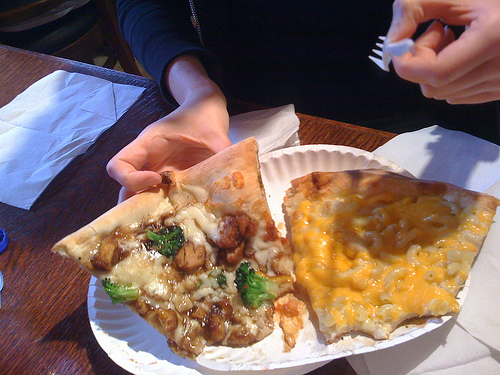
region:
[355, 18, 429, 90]
white plastic fork in hand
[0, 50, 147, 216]
white napkin on wooden table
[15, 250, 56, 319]
wooden surface of table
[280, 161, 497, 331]
macaroni and cheese pizza slive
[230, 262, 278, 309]
green broccoli on pizza slice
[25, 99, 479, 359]
pizza slices on white paper plate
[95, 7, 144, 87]
brown wooden chair leg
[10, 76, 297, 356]
pizza slice being held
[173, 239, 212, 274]
cooked brown mushroom on pizza slice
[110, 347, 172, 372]
food stain on white paper plate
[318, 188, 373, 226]
sauce on a pizza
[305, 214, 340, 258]
sauce on a pizza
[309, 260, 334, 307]
sauce on a pizza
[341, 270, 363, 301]
sauce on a pizza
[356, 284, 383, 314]
sauce on a pizza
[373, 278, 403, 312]
sauce on a pizza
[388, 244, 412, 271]
sauce on a pizza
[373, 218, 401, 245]
sauce on a pizza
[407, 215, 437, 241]
sauce on a pizza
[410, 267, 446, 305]
sauce on a pizza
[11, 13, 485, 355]
Two slices of pizza.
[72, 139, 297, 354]
Slice of pizza with mushrooms, cheese and broccoli.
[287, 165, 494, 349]
Slice of macaroni and cheese pizza.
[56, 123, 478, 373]
Two paper plates holding slices of pizza.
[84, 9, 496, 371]
man preparing to eat pizza.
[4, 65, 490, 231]
White napkins laying on wooden table.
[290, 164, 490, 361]
American cheddar cheese melted on a slice of pizza.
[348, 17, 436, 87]
Man holding a white plastic fork.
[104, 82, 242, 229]
Man holding a slice of veggie pizza.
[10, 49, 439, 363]
Wooden dining table with a plate of pizza on it.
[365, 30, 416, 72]
A plastic fork in a hand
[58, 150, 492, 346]
Two half-eaten slices of pizza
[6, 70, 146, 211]
A single, white napkin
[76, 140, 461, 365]
A plate of half eaten pizza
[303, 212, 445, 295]
Macaroni and cheese topping a pizza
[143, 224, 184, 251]
Broccoli on top of a pizza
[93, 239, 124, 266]
Chicken topping a pizza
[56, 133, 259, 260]
Bread crust of a pizza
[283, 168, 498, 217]
Crust of a slice of pizza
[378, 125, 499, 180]
Napkins on the table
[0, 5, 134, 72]
part of a brown chair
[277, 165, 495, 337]
an eaten slice of pizza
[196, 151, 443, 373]
a white paper plate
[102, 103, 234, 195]
the hand of a person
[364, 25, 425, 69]
a white plastic fork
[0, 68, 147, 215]
a white napkin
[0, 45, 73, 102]
part of a brown table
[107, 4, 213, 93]
the arm of a person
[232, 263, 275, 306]
a piece of broccoli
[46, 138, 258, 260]
pizza crust